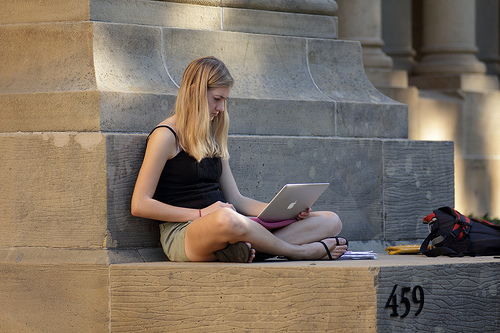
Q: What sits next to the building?
A: The woman.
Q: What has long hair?
A: The woman.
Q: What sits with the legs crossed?
A: The girl.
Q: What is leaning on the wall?
A: The girl.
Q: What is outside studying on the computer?
A: The woman.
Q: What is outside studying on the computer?
A: The lady.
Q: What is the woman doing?
A: Using a computer.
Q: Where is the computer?
A: In the woman's lap.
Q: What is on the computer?
A: An Apple logo.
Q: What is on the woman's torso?
A: A black tank top.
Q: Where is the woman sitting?
A: On the ledge.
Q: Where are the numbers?
A: On the side of the ledge.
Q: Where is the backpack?
A: Next to the woman.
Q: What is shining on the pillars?
A: Sunlight.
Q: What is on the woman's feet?
A: Sandals.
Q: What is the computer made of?
A: Metal.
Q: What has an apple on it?
A: Back of laptop monitor.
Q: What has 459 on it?
A: Stone pedestal of the building.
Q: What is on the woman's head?
A: Blonde hair.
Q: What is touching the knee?
A: The woman's arm.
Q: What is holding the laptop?
A: A person's hand.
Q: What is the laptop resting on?
A: A person's leg.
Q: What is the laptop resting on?
A: The person's leg.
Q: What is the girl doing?
A: Looking at her computer.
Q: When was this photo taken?
A: Daytime.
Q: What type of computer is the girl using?
A: A laptop.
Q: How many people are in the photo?
A: One.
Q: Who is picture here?
A: A girl.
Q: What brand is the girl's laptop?
A: Apple.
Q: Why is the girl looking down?
A: To see her laptop.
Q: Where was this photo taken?
A: In front of a statue.